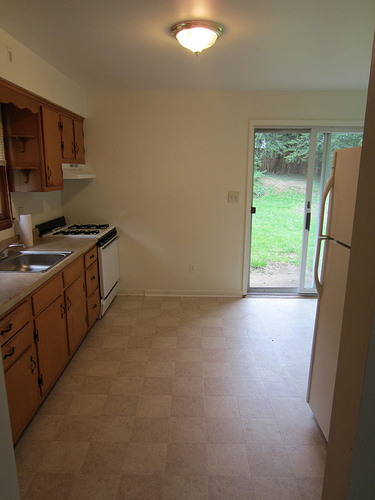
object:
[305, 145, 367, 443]
refrigerator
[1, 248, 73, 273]
sink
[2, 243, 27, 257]
faucet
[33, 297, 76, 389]
door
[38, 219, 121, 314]
oven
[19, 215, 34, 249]
towels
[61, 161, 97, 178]
hood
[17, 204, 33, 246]
paper-towel holder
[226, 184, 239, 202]
switch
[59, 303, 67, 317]
handle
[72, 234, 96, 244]
counter top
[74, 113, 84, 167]
cabinets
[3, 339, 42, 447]
cabinets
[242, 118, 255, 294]
white frame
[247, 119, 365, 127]
white frame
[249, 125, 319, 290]
door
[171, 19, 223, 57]
light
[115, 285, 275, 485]
floor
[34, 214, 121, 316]
range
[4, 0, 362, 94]
ceiling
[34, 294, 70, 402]
cabinet